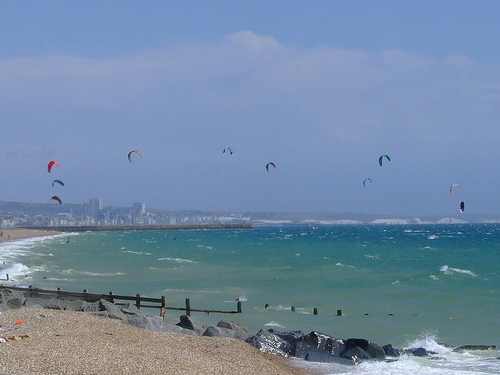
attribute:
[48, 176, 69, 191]
kite — blue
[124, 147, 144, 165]
kite — orange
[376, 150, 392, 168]
kite — green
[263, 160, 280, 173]
kite — rainbow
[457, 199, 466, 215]
kite — black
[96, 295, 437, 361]
rocks — large, gray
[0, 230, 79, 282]
waves — white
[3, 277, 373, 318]
posts — wood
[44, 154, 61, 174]
kite — red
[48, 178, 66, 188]
kite — blue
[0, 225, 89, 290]
waves — big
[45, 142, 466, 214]
kites — ten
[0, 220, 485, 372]
ocean — blue